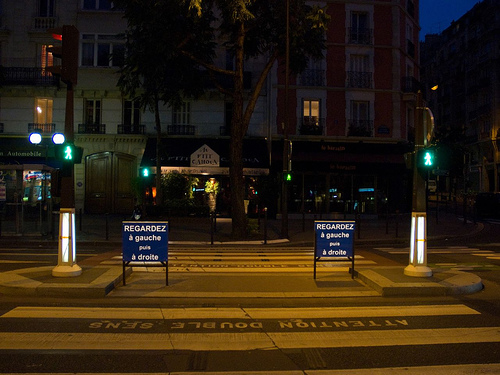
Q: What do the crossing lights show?
A: It's time to walk.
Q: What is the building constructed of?
A: Concrete bricks.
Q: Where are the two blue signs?
A: By the street lights.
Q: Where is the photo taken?
A: In a city.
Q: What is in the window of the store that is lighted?
A: A mannequin.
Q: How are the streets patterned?
A: In stripes.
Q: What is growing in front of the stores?
A: A large tree.